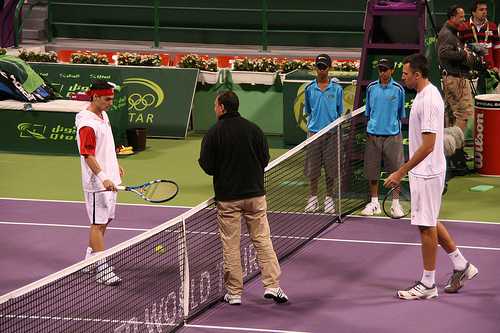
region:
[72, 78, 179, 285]
A man wearing white and red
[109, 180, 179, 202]
A blue and black tennis racket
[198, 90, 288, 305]
A man wearing a black jacket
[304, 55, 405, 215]
A pair of men wearing the same outfit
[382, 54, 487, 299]
A tennis player wearing all white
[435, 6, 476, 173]
Most of a man wearing a gray jacket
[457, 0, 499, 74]
Part of a man wearing red and black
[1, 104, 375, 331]
A net on a tennis court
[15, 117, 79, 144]
Part of a sponsor's logo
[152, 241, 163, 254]
A yellow tennis ball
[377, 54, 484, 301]
Tennis player dressed all in white.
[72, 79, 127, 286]
Tennis player dressed in white with red sleeves and headband.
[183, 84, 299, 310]
Man standing on court talking to a tennis player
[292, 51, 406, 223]
Ball boys wearing brown shorts, blue shirts, white shoes & black baseball caps.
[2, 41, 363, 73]
Flowers on a short wall around the court.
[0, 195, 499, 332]
Tennis court.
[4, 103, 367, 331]
Net stretched across the tennis court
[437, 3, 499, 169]
People standing in the background.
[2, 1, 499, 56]
Railing around the tennis court.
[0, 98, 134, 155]
Table with a banner on it.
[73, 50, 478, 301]
people on a tennis court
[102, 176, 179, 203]
man holding a blue tennis racket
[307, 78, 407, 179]
two young man wearing a uniform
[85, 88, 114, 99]
a red heaband on man's head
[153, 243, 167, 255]
a yellow tennis ball on blue tennis court floor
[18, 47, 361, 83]
a row of white flowers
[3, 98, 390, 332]
a tennis court net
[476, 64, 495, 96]
a black and green bag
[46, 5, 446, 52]
a green metal fence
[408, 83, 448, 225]
man wearing a white shirt and shorts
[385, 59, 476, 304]
man wearing white shoes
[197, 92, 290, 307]
man wearing white shoes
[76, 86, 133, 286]
man wearing white shoes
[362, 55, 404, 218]
man wearing white shoes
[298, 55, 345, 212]
man wearing white shoes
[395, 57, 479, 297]
man wearing white shorts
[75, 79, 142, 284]
man wearing white shorts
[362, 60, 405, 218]
man wearing blue shirt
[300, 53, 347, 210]
man wearing blue shirt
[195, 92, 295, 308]
man wearing tan pants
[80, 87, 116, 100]
Red bandanna on man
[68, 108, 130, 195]
White vest on player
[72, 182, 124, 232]
White and black shorts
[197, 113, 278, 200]
Black jacket on man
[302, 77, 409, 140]
Blue shirts on men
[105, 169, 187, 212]
Tennis racket in man's hand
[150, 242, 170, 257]
Green tennis ball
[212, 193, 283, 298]
khaki pants man is wearing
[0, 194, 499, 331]
Purple colored tennis court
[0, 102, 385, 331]
Tennis court net